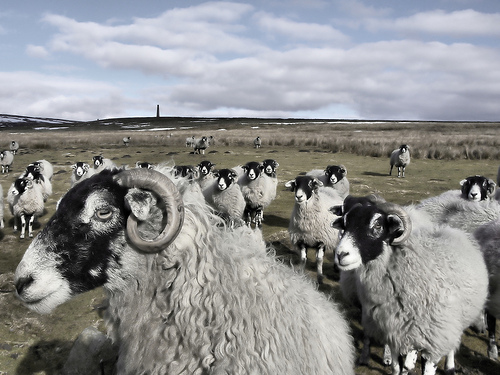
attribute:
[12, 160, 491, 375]
ram — large, twenty, free range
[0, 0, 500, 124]
sky — cloudy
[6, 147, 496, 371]
field — barren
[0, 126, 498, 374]
sheep — free range, many, mountain sheep, lovely, loved, herd, headed, breed, same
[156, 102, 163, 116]
silo — for grain, large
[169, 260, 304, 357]
wool — colored, grey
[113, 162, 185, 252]
horn — large, curlled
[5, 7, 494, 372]
weather — cloudy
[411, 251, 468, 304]
fur — grey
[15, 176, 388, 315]
regions — white, black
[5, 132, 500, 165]
vegetation — brown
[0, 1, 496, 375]
photo — outdoor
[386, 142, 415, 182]
coat — curly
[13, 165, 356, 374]
sheep — closest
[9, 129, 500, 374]
landscape — flat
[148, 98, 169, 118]
structure — tall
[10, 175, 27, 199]
face — black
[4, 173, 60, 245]
coat — curl, pale